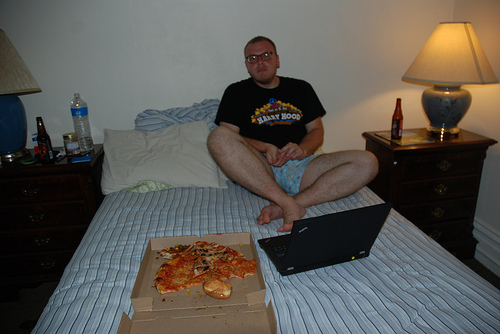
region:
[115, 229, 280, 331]
pizza box on bed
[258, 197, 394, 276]
black laptop on bed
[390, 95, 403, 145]
brown beer bottle on nightstand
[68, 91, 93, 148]
clear water bottle on nightstand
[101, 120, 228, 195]
white pillow next to man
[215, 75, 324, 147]
man wearing black shirt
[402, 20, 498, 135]
lamp turned on on nightstand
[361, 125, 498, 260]
brown nightstand next to bed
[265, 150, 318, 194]
man wearing blue boxers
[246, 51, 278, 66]
man wearing glasses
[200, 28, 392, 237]
Man sitting in bed.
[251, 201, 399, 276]
Black laptop computer sitting on bed.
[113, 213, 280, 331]
Half eaten pizza in box sitting on bed.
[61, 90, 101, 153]
Plastic bottle of water sitting on nightstand.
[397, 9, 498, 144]
Blue lamp sitting on nightstand.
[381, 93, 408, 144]
Bottle of beer sitting on nightstand.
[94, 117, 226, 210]
Pillow with white pillow case laying on bed.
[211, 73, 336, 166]
Man dressed in black t-shirt with colorful emblem on front.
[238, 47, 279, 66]
Man wearing eyeglasses over eyes.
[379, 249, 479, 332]
Blue and gray striped sheet on bed.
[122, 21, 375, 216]
man in blue underwear sitting on bed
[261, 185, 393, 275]
black laptop on bed by man's feet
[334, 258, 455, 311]
blue and white striped bed spread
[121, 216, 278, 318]
half of pizza in pizza box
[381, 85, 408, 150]
brown glass beer bottle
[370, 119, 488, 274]
small brown table near bed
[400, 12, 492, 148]
lamp on table by bed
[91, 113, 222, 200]
white pillow on bed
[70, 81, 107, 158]
plastic bottle of water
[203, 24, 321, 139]
man with glasses and black t-shirt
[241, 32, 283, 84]
the head of a man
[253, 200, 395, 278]
a black laptop computer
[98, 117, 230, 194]
a white pillow on the bed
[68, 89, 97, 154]
a clear plastic bottle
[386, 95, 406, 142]
a brown glass bottle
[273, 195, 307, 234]
the foot of a man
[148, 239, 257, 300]
a pizza in a box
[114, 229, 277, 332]
a brown cardboard box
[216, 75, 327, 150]
a black tee shirt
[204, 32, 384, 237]
a man on the bed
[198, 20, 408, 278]
Man using laptop on bed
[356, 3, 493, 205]
beer and lamp on nightstand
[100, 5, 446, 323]
Man in boxers with computer and pizza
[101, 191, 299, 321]
dinner in bed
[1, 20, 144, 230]
lamp, beer and water on nightstand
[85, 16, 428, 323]
man relaxing on bed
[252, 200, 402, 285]
laptop on bed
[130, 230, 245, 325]
pizza box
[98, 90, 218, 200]
pillow on bed